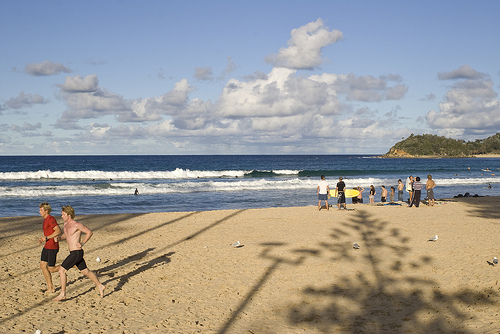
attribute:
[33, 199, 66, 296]
man — running, shoeless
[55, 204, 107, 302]
man — running, topless, shoeless, bare chested, bare footed, shirtless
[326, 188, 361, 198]
surfboard — yellow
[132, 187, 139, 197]
man — swimming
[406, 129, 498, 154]
trees — green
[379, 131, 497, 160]
mountain — distant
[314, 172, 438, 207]
people — here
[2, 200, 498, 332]
beach — here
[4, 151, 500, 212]
water — blue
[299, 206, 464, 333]
shadow — dark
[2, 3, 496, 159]
sky — blue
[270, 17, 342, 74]
clouds — white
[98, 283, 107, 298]
foot — behind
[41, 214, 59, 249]
shirt — red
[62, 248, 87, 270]
shorts — black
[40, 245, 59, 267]
shorts — black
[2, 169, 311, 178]
waves — white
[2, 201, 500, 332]
sand — tan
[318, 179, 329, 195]
shirt — white